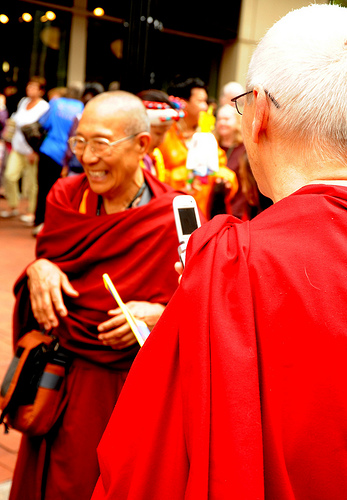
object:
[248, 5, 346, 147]
hair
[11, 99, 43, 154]
shirt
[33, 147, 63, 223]
pants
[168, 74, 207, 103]
hair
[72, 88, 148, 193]
head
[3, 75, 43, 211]
woman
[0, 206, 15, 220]
shoe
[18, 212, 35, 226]
shoe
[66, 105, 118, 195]
face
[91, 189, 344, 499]
cloak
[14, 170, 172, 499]
robe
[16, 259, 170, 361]
hands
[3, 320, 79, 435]
bag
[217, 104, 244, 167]
woman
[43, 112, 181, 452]
man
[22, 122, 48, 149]
purse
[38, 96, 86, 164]
blue shirt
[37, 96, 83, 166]
tshirt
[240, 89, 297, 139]
ear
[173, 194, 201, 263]
cell phone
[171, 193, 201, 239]
top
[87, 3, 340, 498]
monk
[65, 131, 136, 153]
glasses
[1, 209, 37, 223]
shoes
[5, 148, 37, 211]
beige pants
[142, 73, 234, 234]
couple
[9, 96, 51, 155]
t-shirt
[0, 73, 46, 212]
person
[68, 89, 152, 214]
skin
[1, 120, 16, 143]
bag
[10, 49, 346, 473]
two monks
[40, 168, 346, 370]
garments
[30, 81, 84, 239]
person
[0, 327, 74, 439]
case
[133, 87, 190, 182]
woman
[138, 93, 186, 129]
head dress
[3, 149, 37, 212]
pants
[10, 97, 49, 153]
tshirt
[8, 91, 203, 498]
monk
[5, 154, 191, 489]
cape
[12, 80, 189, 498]
person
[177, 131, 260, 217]
clothes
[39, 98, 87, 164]
shirt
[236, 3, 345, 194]
head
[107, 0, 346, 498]
man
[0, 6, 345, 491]
crowd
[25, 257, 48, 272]
wrist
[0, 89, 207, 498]
body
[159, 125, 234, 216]
costume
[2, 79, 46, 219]
person